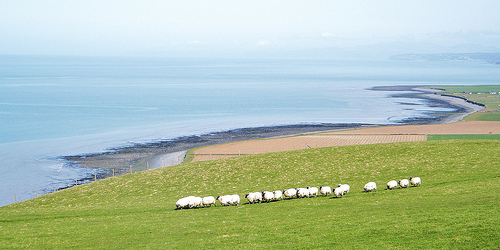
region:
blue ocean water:
[9, 41, 488, 161]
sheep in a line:
[168, 172, 440, 201]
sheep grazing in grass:
[144, 177, 467, 222]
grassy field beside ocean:
[61, 157, 438, 248]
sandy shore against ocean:
[168, 113, 479, 149]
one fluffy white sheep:
[354, 170, 384, 200]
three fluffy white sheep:
[383, 176, 425, 191]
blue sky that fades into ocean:
[11, 12, 488, 138]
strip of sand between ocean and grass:
[421, 77, 485, 139]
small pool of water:
[138, 135, 195, 179]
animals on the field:
[290, 161, 423, 235]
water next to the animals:
[80, 55, 183, 135]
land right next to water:
[242, 122, 287, 162]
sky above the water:
[130, 5, 181, 45]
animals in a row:
[215, 155, 380, 242]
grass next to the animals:
[301, 202, 361, 237]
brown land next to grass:
[367, 125, 407, 140]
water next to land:
[71, 90, 121, 131]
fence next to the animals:
[104, 157, 164, 189]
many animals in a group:
[172, 141, 439, 230]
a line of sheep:
[183, 171, 436, 208]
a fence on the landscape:
[0, 121, 499, 206]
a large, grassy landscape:
[4, 130, 498, 248]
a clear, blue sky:
[6, 5, 495, 60]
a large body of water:
[1, 55, 426, 212]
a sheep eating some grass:
[356, 175, 373, 190]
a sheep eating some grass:
[170, 190, 185, 210]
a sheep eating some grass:
[185, 190, 200, 206]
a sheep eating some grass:
[385, 177, 398, 192]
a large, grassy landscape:
[442, 80, 499, 123]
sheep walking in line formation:
[164, 167, 439, 213]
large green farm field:
[57, 102, 490, 234]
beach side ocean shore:
[371, 80, 492, 137]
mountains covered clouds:
[354, 28, 496, 71]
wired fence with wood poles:
[2, 154, 215, 221]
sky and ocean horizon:
[7, 29, 193, 87]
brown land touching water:
[187, 112, 479, 170]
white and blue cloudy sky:
[89, 7, 297, 73]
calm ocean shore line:
[39, 74, 298, 149]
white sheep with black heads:
[166, 168, 428, 213]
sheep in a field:
[405, 172, 426, 188]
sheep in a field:
[395, 175, 410, 190]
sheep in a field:
[380, 177, 400, 190]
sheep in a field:
[360, 175, 380, 197]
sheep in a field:
[335, 178, 352, 194]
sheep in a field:
[330, 183, 345, 199]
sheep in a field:
[316, 180, 332, 200]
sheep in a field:
[305, 180, 318, 203]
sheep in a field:
[291, 183, 306, 196]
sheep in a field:
[281, 184, 299, 201]